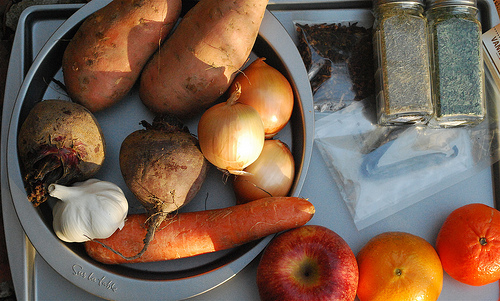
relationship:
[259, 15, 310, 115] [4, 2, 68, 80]
tin on tray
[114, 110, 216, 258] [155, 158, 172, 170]
beet covered in dirt